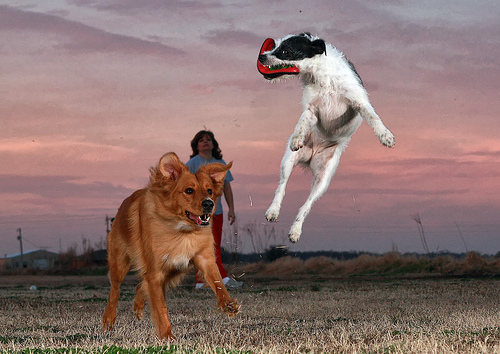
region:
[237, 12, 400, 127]
Black and white dog catching a frisbee.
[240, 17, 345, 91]
A red frisbee in the dogs mouth.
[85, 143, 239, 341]
A brown dog running through a field.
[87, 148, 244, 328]
The brown dog was photo shopped into the picture.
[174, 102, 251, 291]
A woman out for a stroll.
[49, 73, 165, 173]
A pink sky says it's coming up on twilight.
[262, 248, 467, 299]
Some scrub bushes in the distance.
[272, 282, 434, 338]
Dried brown grass in the field.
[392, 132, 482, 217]
A few clouds in the pink sky.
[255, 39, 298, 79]
red boomerang in dog's mouth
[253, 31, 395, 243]
dog with a boomerang in its mouth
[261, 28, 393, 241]
black and white dog bitting a boomerang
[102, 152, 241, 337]
brown dog caught in the air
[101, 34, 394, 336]
two dogs caught jumping in the air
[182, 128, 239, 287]
woman in the background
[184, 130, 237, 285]
woman wearing a blue shirt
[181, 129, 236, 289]
woman wearing red pants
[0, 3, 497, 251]
Sky showing the sunset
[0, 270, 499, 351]
dry brown grass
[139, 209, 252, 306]
this is a leg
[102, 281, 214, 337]
this is a dog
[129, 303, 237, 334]
this is a paw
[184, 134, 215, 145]
this is a woman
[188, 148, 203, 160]
this is a shirt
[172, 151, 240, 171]
the shirt is blue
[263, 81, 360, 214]
this is a white dog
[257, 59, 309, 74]
this is a frisbee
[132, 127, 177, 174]
this is an ear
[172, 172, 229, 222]
this is an eye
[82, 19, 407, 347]
Two dogs playing frisbee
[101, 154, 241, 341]
A brown dog in the air.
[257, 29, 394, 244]
A dog catching a frisbee.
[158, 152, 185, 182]
The dog's ear.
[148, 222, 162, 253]
Part of the dog's brown fur.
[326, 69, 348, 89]
Part of the dog's white fur.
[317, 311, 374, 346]
Part of the grass.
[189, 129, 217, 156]
The head of the woman.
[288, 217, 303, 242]
The dog's white paw.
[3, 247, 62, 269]
A building in the background.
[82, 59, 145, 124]
Part fo the sky.